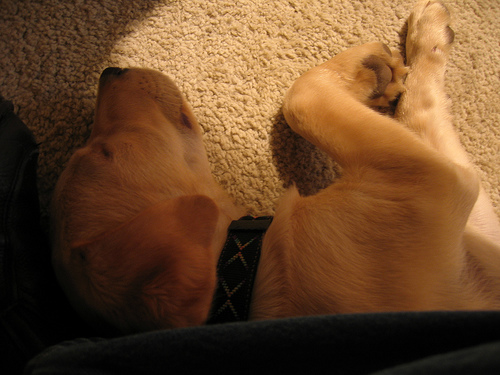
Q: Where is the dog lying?
A: On floor.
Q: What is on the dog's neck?
A: Collar.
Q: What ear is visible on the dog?
A: Right ear.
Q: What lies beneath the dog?
A: Carpet.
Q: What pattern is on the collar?
A: X shapes.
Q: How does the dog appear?
A: Sleeping.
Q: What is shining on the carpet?
A: Sunlight.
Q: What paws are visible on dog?
A: Front paws.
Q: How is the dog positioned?
A: Sideways.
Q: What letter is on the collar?
A: X.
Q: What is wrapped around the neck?
A: A collar.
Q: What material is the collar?
A: Leather.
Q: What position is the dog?
A: Lying down.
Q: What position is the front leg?
A: Bent.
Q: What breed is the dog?
A: Lab.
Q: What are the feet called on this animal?
A: Paws.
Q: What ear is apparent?
A: The right.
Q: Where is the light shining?
A: On the carpet.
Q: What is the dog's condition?
A: Asleep.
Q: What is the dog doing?
A: Sleeping.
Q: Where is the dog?
A: On the carpet.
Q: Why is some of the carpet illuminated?
A: Sunlight.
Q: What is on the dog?
A: A dog collar.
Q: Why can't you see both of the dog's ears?
A: The dog is sleeping on one ear.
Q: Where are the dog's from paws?
A: Resting on the floor.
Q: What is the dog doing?
A: Laying down.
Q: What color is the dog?
A: Brown.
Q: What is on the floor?
A: Carpet.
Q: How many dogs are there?
A: One.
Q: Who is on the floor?
A: The dog.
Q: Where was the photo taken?
A: Near dog.